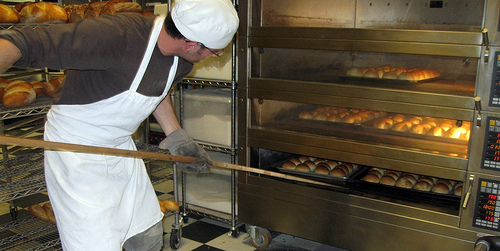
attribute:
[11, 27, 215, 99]
sweater — brown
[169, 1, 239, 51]
hat — white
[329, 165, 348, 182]
roll — baked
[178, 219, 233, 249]
floor — checkered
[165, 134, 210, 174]
glove — grey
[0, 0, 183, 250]
rack — metal, wire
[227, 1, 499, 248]
oven — silver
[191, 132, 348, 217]
handle — wood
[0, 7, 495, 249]
bakery — commercial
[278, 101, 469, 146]
bread — baking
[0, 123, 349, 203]
stick — long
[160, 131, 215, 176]
hand — man's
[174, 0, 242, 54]
cap — white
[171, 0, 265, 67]
hat — white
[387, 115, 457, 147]
bread — fresh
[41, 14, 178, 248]
apron — white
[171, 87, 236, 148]
box — white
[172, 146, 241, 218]
box — white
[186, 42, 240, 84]
box — white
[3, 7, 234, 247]
man — cooking